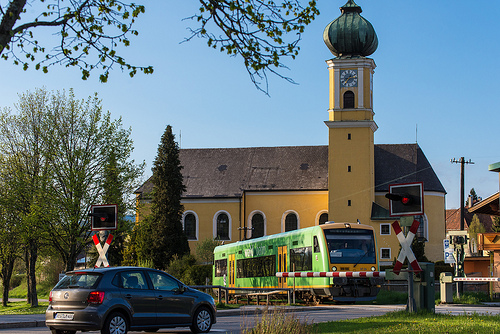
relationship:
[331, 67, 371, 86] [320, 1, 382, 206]
clock on tower